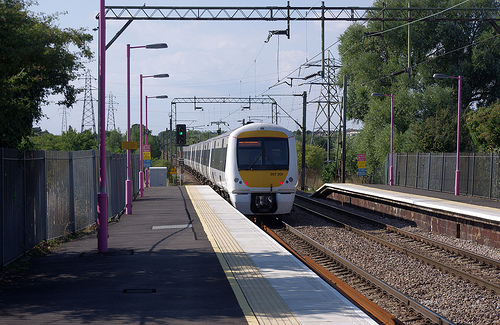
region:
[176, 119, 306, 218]
a yellow and white commuter train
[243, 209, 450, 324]
a set of train tracks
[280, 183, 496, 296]
a set of train tracks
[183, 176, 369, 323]
a white train boarding platform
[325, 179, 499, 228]
a white train boarding platform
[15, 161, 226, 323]
a paved sidewalk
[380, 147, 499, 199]
black metal protective fencing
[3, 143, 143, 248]
black metal protective fencing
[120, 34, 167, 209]
tall overhead light pole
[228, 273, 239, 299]
the line is yellow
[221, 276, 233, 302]
the line is yellow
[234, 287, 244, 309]
the line is yellow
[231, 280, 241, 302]
the line is yellow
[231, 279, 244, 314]
the line is yellow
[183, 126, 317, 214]
the train is white and yellow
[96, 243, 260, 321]
shadow is on the ground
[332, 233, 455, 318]
gravel is betwween the tracks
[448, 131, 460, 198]
the pole is purple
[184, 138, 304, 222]
the train is electric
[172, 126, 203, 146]
the traffic sign is green for go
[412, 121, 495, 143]
trees are in the background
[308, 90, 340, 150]
the structure is mettalic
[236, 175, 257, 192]
the lights are red in color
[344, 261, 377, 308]
the metal rail is rusted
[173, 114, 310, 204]
a long yellow and white train.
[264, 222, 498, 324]
a train track near a loading platform.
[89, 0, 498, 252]
a purple over hang.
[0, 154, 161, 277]
a fence near train tracks.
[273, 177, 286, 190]
a red light on a train.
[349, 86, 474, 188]
a large leafy tree.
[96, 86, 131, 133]
a very tall power line.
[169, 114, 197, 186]
a green light near a train.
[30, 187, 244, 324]
a walkway near a train.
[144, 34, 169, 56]
a light suspended over tracks.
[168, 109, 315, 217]
The train is white.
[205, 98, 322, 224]
The train has yellow accents.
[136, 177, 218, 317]
The platform is empty.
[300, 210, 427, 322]
The track has rocks on it.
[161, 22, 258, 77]
The sky is white and blue.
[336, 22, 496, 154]
The tree is green and leafy.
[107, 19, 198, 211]
The lights are tall.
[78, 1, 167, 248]
The lights are off.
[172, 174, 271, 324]
The platform is white and tan.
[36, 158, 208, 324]
The shadow is large.